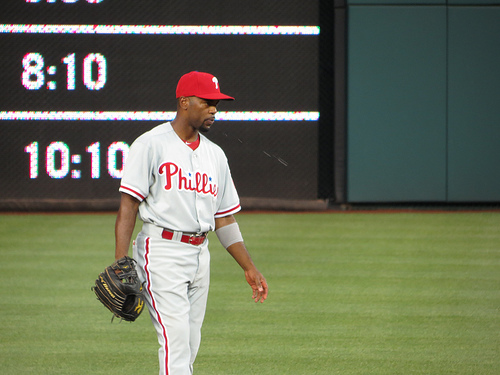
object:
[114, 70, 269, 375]
man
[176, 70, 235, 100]
cap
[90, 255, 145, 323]
glove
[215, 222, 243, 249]
band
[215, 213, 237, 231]
elbow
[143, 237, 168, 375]
stripe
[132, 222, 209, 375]
pants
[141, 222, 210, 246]
belt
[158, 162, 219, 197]
team name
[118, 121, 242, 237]
jersey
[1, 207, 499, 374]
field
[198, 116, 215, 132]
facial hair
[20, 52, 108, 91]
time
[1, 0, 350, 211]
scoreboard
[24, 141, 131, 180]
time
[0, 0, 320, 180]
lights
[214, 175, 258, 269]
left arm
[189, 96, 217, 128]
face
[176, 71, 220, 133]
head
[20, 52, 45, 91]
numbers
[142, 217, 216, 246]
waist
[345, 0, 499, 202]
wall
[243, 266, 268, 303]
hand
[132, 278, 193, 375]
leg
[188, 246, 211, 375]
leg